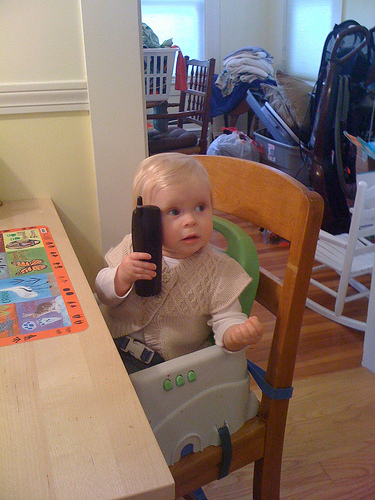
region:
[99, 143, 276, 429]
blonde child sitting in booster seat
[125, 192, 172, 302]
black cordless phone in child's hand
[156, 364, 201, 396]
green buttons on booster seat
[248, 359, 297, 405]
blue strap on wood chair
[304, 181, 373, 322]
white wood rocking chair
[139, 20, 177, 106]
laundry in a white basket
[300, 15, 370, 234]
upright vacuum cleaner on floor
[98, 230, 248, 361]
knitted tan vest on child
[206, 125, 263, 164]
white garbage bag with red ties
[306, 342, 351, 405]
two types of hardwood floor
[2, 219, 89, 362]
a children's place mat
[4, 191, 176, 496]
wooden kitchen table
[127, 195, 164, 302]
black wireless telephone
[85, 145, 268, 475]
a toddler in a high chair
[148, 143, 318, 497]
a brown wooden chair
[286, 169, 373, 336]
small white rocking chair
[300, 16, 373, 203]
black mesh play pen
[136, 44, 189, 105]
white plastic laundry basket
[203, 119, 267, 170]
white trash bag with a red tie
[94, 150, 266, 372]
a toddler holding a cellphone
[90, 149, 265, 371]
a toddler wearing a beige sweater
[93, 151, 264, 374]
a toddler wearing a white, long sleeved shirt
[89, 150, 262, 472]
a toddler sitting in a booster seat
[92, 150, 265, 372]
a toddler with blonde hair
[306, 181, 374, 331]
a white wooden rocking chair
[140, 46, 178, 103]
a white plastic clothes basket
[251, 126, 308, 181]
a blue plastic storage container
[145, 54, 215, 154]
a brown wooden chair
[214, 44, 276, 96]
a pile of folded clothes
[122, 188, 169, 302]
a black telephone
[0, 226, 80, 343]
a colorful placemat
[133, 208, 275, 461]
the baby's booster seat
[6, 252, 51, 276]
a monarch butterfly on the placemat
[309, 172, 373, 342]
a white, wooden rocking chair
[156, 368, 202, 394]
three green buttons on the booster seat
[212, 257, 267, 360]
the child's left arm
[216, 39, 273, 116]
a pile of folded laundry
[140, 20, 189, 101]
a laundry basket on the table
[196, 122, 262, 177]
a full trashbag with a red plastic handle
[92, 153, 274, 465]
baby sitting in a booster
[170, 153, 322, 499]
plastic booster seat is strapped to a wooden chair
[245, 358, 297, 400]
blue nylon strap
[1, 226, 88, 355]
plastic placemat on wooden table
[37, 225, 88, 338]
orange border around placemat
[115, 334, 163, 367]
white buckle around waist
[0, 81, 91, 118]
chair rail on wall behind kitchen table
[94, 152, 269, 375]
baby is sitting at the table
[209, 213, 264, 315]
the back of the booster is green plastic